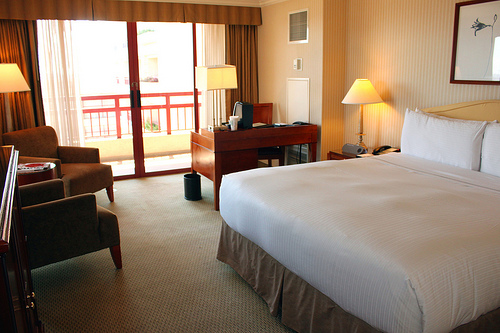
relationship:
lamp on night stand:
[340, 78, 383, 153] [326, 144, 376, 159]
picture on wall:
[449, 0, 499, 86] [346, 0, 500, 149]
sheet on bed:
[219, 152, 498, 332] [217, 99, 498, 331]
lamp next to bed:
[340, 78, 383, 153] [217, 99, 498, 331]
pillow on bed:
[401, 107, 487, 172] [217, 99, 498, 331]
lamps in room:
[2, 61, 384, 152] [0, 0, 499, 332]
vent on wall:
[288, 7, 309, 46] [254, 1, 323, 167]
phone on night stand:
[372, 145, 401, 158] [326, 144, 376, 159]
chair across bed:
[0, 124, 115, 206] [217, 99, 498, 331]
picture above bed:
[449, 0, 499, 86] [217, 99, 498, 331]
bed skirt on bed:
[216, 213, 499, 332] [217, 99, 498, 331]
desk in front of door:
[190, 121, 317, 210] [72, 21, 201, 179]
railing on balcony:
[79, 89, 201, 139] [79, 93, 202, 179]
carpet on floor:
[28, 170, 296, 331] [30, 170, 296, 330]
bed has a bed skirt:
[217, 99, 498, 331] [216, 213, 499, 332]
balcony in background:
[79, 93, 202, 179] [33, 9, 325, 239]